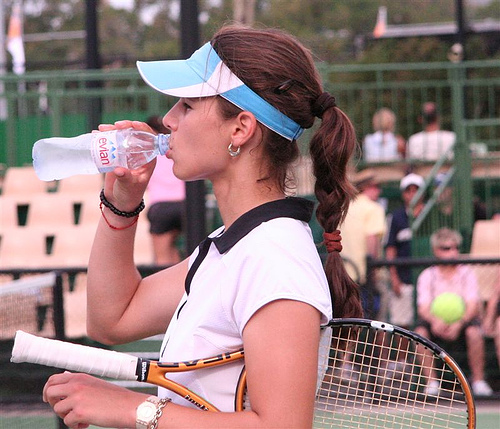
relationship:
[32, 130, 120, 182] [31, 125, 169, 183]
water in in a bottle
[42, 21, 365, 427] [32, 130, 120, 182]
woman drinking water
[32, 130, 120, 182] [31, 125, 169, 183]
water in a bottle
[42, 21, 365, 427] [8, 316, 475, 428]
woman holding racket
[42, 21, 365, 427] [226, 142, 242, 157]
woman wearing earring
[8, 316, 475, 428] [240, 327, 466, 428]
racket has strings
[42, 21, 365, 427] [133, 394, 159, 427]
woman wearing a watch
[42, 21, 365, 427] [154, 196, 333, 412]
woman wearing a shirt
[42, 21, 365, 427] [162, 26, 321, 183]
woman has a head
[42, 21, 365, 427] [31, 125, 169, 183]
woman drinking from a bottle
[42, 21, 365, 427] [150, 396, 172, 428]
woman wearing a bracelet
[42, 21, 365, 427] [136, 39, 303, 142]
woman wearing a visor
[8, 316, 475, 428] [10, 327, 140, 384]
racket has a handle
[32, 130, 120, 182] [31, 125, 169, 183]
water in bottle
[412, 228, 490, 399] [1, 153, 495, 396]
woman sitting on stands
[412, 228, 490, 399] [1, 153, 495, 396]
woman sitting in stands